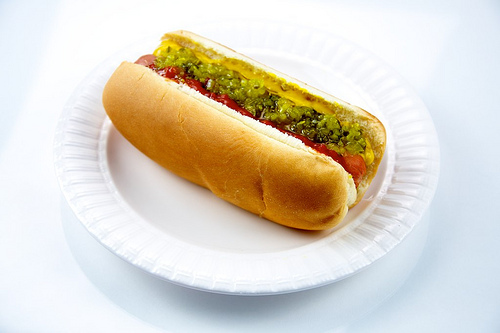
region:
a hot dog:
[95, 20, 390, 228]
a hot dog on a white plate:
[55, 25, 433, 285]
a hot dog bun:
[100, 66, 181, 157]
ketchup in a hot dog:
[162, 66, 192, 82]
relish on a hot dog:
[211, 67, 241, 92]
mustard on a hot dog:
[230, 60, 256, 77]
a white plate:
[48, 170, 165, 292]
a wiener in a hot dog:
[346, 151, 368, 182]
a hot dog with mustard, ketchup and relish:
[97, 20, 383, 221]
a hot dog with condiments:
[96, 23, 401, 238]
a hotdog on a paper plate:
[41, 15, 446, 302]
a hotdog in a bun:
[104, 26, 389, 231]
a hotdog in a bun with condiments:
[98, 23, 387, 235]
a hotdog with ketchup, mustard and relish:
[301, 104, 393, 233]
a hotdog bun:
[285, 138, 362, 238]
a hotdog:
[350, 156, 370, 184]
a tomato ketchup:
[290, 136, 335, 159]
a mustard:
[155, 40, 170, 51]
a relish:
[241, 84, 268, 105]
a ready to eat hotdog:
[94, 24, 394, 299]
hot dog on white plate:
[53, 20, 449, 299]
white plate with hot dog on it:
[87, 18, 442, 293]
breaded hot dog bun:
[105, 135, 332, 225]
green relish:
[192, 58, 232, 78]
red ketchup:
[162, 67, 198, 85]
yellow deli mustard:
[153, 30, 178, 50]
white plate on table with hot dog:
[23, 10, 494, 309]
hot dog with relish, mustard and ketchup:
[109, 31, 391, 228]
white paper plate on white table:
[15, 18, 472, 331]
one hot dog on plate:
[85, 32, 443, 269]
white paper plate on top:
[200, 255, 232, 267]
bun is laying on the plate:
[222, 141, 250, 174]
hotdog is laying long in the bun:
[357, 164, 365, 172]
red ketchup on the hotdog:
[166, 65, 184, 80]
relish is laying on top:
[200, 76, 239, 80]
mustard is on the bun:
[297, 91, 307, 101]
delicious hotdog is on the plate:
[98, 31, 400, 228]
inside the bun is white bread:
[248, 127, 293, 141]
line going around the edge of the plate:
[67, 197, 132, 211]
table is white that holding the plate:
[450, 291, 473, 308]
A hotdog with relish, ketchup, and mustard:
[100, 17, 390, 234]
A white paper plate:
[46, 11, 441, 297]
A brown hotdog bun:
[97, 25, 387, 240]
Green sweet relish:
[155, 35, 370, 155]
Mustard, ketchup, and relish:
[136, 26, 383, 186]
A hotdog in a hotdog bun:
[97, 17, 399, 238]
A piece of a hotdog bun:
[101, 58, 361, 235]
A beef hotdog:
[132, 50, 378, 180]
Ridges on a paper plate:
[372, 187, 443, 237]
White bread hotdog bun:
[101, 19, 391, 234]